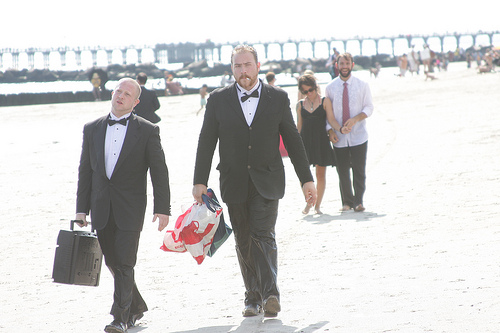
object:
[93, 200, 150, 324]
pants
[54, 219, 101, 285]
briefcase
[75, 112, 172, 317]
suit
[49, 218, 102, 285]
case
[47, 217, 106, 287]
stereo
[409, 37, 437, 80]
person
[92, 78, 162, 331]
man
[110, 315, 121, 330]
foot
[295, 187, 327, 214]
foot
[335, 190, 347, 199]
foot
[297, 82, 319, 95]
sunglasses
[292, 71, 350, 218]
girl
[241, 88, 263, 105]
bow tie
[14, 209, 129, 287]
radio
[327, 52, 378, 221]
man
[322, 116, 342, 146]
hands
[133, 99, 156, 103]
ear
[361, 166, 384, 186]
ground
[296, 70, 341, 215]
person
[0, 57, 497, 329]
beach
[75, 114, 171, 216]
black jacket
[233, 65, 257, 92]
cigarette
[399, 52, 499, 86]
people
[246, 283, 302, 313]
shoe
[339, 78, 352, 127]
tie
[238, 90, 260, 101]
bowtie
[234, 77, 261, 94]
neck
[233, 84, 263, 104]
tie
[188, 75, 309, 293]
coat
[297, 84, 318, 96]
sun shades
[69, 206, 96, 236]
hand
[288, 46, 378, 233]
couple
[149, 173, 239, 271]
bags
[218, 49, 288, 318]
man